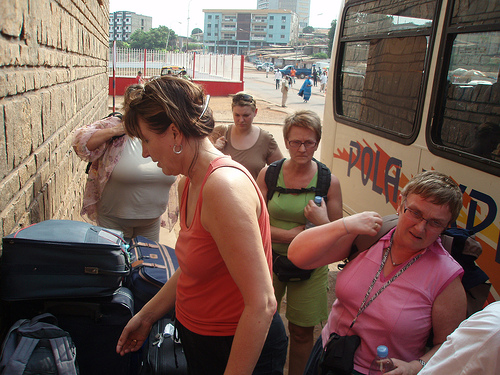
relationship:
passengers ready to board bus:
[128, 79, 284, 371] [333, 0, 498, 173]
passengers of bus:
[128, 79, 284, 371] [333, 0, 498, 173]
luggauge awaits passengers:
[2, 217, 135, 304] [128, 79, 284, 371]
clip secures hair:
[196, 93, 213, 121] [120, 74, 216, 145]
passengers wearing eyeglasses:
[268, 107, 340, 219] [284, 136, 319, 150]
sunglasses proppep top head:
[399, 194, 452, 233] [394, 169, 465, 252]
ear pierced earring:
[168, 121, 187, 147] [171, 143, 185, 155]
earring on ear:
[395, 211, 399, 216] [392, 191, 404, 214]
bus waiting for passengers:
[333, 0, 498, 173] [128, 79, 284, 371]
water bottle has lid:
[368, 345, 397, 374] [375, 344, 391, 358]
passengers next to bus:
[268, 107, 340, 219] [333, 0, 498, 173]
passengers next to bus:
[128, 79, 284, 371] [333, 0, 498, 173]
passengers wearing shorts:
[268, 107, 340, 219] [265, 247, 331, 329]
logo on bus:
[333, 136, 499, 311] [333, 0, 498, 173]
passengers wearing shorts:
[128, 79, 284, 371] [169, 309, 292, 373]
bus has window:
[333, 0, 498, 173] [332, 0, 440, 145]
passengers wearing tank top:
[128, 79, 284, 371] [173, 152, 276, 337]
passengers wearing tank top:
[268, 107, 340, 219] [263, 163, 335, 280]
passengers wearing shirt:
[221, 89, 272, 160] [209, 124, 280, 186]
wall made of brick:
[1, 1, 111, 238] [18, 155, 38, 188]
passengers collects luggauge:
[128, 79, 284, 371] [2, 217, 135, 304]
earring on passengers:
[171, 143, 185, 155] [128, 79, 284, 371]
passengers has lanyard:
[348, 170, 465, 325] [350, 232, 427, 325]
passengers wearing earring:
[128, 79, 284, 371] [171, 143, 185, 155]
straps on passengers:
[263, 156, 332, 212] [268, 107, 340, 219]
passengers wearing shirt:
[348, 170, 465, 325] [320, 219, 470, 373]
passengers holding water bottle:
[348, 170, 465, 325] [368, 345, 397, 374]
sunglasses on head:
[399, 194, 452, 233] [394, 169, 465, 252]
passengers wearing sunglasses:
[348, 170, 465, 325] [399, 194, 452, 233]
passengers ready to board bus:
[348, 170, 465, 325] [333, 0, 498, 173]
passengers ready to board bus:
[268, 107, 340, 219] [333, 0, 498, 173]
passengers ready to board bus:
[221, 89, 272, 160] [333, 0, 498, 173]